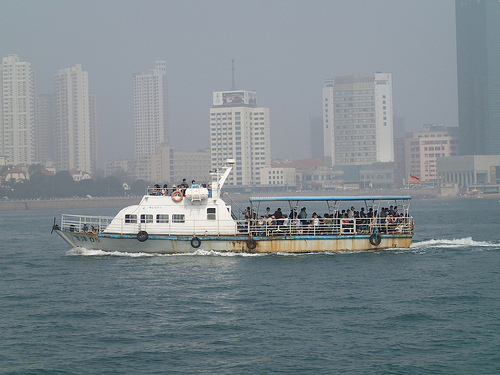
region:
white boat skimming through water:
[57, 164, 419, 263]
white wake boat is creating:
[418, 228, 493, 258]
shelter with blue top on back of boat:
[237, 188, 419, 238]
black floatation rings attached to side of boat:
[126, 227, 416, 259]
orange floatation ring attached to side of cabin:
[170, 185, 189, 210]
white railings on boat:
[56, 210, 409, 239]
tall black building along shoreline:
[448, 13, 499, 148]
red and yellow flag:
[406, 172, 419, 187]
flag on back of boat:
[400, 170, 430, 212]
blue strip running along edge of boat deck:
[56, 226, 408, 239]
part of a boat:
[186, 220, 206, 238]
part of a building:
[253, 143, 273, 158]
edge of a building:
[243, 115, 254, 155]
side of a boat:
[151, 225, 185, 240]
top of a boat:
[202, 182, 219, 196]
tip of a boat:
[63, 218, 81, 227]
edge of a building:
[420, 148, 424, 175]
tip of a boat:
[148, 205, 173, 234]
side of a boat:
[76, 229, 87, 251]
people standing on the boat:
[230, 195, 416, 233]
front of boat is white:
[104, 173, 266, 230]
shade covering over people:
[238, 180, 417, 214]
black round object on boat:
[174, 223, 219, 259]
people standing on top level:
[142, 172, 198, 201]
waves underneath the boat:
[53, 238, 128, 266]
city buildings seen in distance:
[6, 35, 493, 226]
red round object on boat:
[162, 182, 187, 208]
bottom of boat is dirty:
[245, 225, 425, 263]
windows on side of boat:
[111, 198, 243, 234]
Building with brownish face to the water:
[332, 79, 378, 163]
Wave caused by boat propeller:
[414, 236, 499, 248]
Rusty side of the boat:
[261, 241, 365, 251]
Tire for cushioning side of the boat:
[244, 238, 260, 251]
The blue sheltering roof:
[246, 195, 411, 203]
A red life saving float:
[169, 186, 185, 203]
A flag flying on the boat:
[407, 172, 421, 186]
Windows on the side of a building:
[381, 91, 388, 131]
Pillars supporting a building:
[461, 172, 473, 191]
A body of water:
[105, 280, 308, 332]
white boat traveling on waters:
[51, 171, 419, 258]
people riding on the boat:
[54, 168, 404, 238]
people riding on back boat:
[246, 204, 407, 238]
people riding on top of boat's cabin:
[145, 169, 213, 198]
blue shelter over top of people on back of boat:
[245, 191, 412, 211]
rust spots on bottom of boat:
[177, 235, 408, 250]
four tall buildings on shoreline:
[1, 52, 402, 185]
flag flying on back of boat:
[409, 170, 424, 197]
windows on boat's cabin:
[121, 206, 233, 224]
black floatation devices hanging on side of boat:
[131, 227, 382, 253]